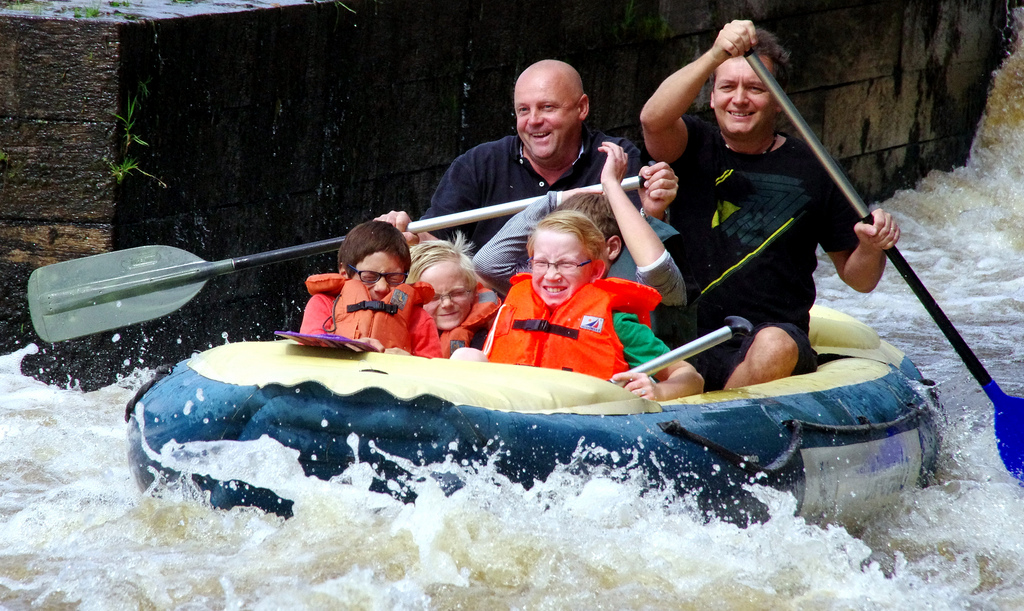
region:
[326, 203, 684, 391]
Four kids on the raft.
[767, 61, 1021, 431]
The man is holding an oar.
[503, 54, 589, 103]
The man has a bald head.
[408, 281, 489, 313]
The kid eyes are closed.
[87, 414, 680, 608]
Water is splashing in front of the boat.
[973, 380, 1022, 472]
The end of the paddle is blue.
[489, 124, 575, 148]
The man is smiling.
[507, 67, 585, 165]
the man is smiling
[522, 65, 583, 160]
the man is bald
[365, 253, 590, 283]
the children are wearing glasses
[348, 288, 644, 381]
the vests are orange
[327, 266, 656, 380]
children in the life vests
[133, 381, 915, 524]
the raft is blue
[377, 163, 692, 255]
the handle is tan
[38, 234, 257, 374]
the paddle blade is black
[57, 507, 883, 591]
the water is white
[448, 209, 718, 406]
child with orange life jacket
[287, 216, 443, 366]
child with orange life jacket and glasses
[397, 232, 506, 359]
small child with blonde hair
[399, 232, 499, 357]
small child with life jacket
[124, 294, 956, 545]
blue and white water raft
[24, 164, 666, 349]
a long boat paddle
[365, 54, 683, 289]
man with blue sweater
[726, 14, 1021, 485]
man with boat paddle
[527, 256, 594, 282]
The eyeglasses the kid on the left is wearing.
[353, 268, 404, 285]
The eyeglasses the kid with brown hair is wearing.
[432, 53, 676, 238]
The bald head man on the left.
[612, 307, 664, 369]
The green shirt sleeve of the boy on the right.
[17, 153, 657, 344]
The oar in the hands of the man on the left.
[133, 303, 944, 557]
The raft the kids and men are in.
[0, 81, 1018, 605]
The water surrounding the raft the group is in.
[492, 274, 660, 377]
The life jacket the kid with the green sleeve is wearing.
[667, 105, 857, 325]
The black t-shirt the man is wearing.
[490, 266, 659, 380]
an orange life vest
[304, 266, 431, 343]
an orange life vest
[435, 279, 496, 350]
an orange life vest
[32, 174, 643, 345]
a long boat oar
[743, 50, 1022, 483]
a long boat oar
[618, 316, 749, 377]
an oar handle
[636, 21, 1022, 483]
a man paddling a boat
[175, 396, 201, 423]
white water in air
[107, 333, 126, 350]
white water in air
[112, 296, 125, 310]
white water in air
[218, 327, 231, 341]
white water in air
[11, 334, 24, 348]
white water in air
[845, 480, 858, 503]
white water in air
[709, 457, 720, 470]
white water in air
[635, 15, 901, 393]
man smiling in large raft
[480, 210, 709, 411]
kid with glasses wearing life jacket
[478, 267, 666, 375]
life jacket on kid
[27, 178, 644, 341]
long large green paddle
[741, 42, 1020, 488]
long large blue paddle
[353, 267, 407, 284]
small round pair of glasses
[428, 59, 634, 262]
man riding in a raft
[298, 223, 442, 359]
small boy in raft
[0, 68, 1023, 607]
large open wide water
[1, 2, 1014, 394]
large wide brick wall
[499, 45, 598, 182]
part of human body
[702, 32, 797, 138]
part of human body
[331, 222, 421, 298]
part of human body